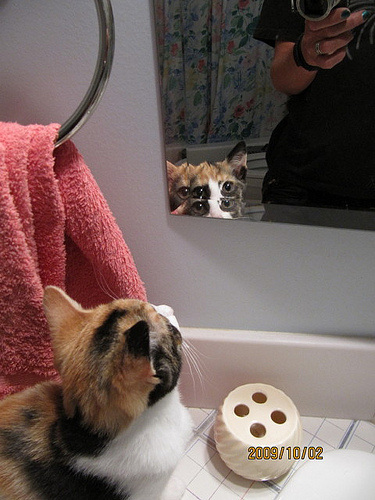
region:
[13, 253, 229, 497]
this is a cat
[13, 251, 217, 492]
the cat is looking up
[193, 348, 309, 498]
this is a toothbrush holder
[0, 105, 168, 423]
this is a towel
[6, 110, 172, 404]
the towel is pink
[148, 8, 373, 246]
this is a mirror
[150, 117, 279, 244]
cat reflection in the mirror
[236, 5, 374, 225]
person in mirror reflection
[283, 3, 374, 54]
this is a camera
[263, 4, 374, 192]
person wearing a black shirt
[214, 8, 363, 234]
this is a person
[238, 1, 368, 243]
person reflection in mirror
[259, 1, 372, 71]
person holding a camera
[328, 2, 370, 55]
person wearing blue nailpolish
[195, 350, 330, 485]
this is a toothbrush holder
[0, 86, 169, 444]
this is a towel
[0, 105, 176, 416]
the towel is pink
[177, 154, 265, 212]
a cat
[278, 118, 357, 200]
the mirror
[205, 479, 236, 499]
tile on the floor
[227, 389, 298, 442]
a toothbrush holder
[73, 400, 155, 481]
the cats fur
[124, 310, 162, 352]
the cats ear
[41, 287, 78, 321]
the cats ear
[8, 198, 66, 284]
a red towel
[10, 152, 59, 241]
a towel that is red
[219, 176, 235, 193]
a cats eye in the mirror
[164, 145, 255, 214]
a cat sees itself in a beveled glass mirror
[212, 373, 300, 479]
a toothbrush holder for four brushes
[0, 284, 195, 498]
a calico cat in the bathroom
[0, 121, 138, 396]
a coral colored towel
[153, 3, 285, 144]
a floral patterned shower curtain.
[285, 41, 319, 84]
a black wrist watch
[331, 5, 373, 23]
woman wears dark nail polish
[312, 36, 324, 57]
a wedding ring on her left hand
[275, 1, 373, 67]
the photographer holding her camera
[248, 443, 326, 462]
the date of the picture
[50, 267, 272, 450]
a cat in the bathroom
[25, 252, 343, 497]
a cat inside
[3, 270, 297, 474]
a cat sitting inside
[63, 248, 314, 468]
a cat sitting in a bathroom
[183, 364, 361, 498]
a toothrbush holder in the bathroom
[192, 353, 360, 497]
a glass toothrbush holder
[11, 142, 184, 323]
a towel hangin on the wall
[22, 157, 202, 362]
a towel in the bathroom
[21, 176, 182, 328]
a bathroom with a towel